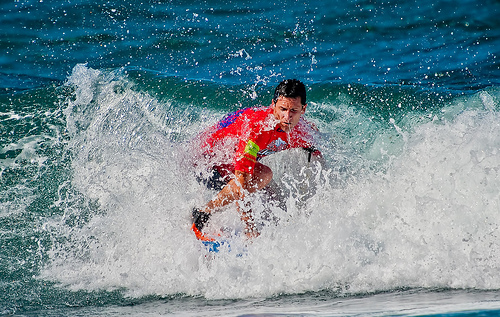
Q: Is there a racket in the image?
A: No, there are no rackets.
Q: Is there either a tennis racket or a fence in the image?
A: No, there are no rackets or fences.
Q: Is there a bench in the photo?
A: No, there are no benches.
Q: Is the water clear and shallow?
A: Yes, the water is clear and shallow.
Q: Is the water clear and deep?
A: No, the water is clear but shallow.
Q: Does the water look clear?
A: Yes, the water is clear.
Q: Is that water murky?
A: No, the water is clear.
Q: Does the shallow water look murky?
A: No, the water is clear.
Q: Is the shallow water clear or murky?
A: The water is clear.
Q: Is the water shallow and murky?
A: No, the water is shallow but clear.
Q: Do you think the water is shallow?
A: Yes, the water is shallow.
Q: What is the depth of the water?
A: The water is shallow.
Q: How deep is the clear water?
A: The water is shallow.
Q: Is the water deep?
A: No, the water is shallow.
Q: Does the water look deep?
A: No, the water is shallow.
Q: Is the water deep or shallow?
A: The water is shallow.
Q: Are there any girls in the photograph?
A: No, there are no girls.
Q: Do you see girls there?
A: No, there are no girls.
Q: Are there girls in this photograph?
A: No, there are no girls.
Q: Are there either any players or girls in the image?
A: No, there are no girls or players.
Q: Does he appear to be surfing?
A: Yes, the man is surfing.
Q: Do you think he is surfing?
A: Yes, the man is surfing.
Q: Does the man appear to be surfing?
A: Yes, the man is surfing.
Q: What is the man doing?
A: The man is surfing.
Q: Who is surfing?
A: The man is surfing.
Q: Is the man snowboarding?
A: No, the man is surfing.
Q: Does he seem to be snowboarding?
A: No, the man is surfing.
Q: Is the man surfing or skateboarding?
A: The man is surfing.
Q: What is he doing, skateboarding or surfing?
A: The man is surfing.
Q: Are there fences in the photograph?
A: No, there are no fences.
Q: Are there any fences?
A: No, there are no fences.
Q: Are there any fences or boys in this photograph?
A: No, there are no fences or boys.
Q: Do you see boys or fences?
A: No, there are no fences or boys.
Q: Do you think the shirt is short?
A: Yes, the shirt is short.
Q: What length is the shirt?
A: The shirt is short.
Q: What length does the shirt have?
A: The shirt has short length.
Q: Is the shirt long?
A: No, the shirt is short.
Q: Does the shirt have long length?
A: No, the shirt is short.